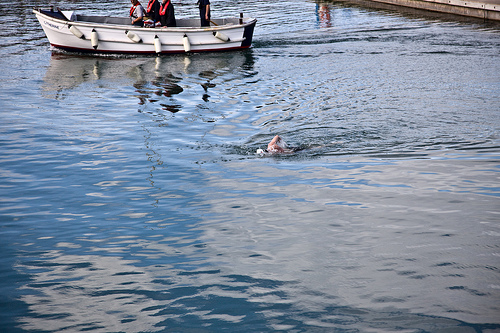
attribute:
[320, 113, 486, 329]
water — calm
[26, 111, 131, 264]
water — calm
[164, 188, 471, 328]
water — blue, sea water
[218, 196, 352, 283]
water — blue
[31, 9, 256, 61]
boat — small, white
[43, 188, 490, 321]
waves — small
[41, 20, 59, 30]
writing — black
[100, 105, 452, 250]
water — calm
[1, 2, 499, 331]
water — calm, rough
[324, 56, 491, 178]
water — calm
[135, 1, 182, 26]
vest — red, life vest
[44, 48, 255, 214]
reflection — boat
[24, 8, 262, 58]
boat — white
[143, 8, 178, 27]
clothing — black